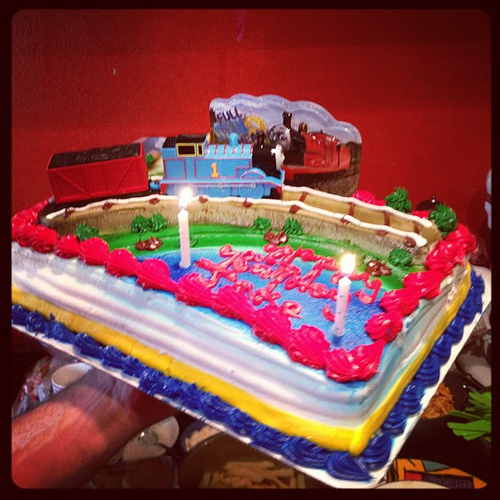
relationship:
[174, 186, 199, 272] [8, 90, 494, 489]
candle on cake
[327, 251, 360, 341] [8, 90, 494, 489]
candle on cake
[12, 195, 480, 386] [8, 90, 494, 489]
icing on cake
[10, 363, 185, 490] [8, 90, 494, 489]
someone holding cake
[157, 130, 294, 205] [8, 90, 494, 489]
train on cake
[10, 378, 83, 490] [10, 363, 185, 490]
arm on someone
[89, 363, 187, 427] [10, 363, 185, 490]
hand on someone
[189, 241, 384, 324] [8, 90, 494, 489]
writing on cake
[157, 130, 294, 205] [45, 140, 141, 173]
train hauling coal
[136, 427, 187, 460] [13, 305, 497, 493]
spoon on table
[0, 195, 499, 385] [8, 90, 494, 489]
icing on cake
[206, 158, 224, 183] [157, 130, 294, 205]
number on train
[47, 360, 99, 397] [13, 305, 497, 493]
cup on table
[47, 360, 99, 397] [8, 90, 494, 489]
cup beneath cake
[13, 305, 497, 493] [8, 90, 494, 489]
table beneath cake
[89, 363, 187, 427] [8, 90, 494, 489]
hand carrying cake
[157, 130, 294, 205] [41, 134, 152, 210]
train pulling car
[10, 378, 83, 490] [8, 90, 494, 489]
arm holding cake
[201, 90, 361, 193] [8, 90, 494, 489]
illustration behind cake